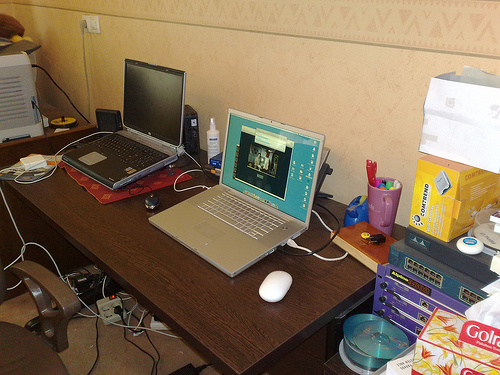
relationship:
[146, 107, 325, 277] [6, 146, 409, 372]
laptop on table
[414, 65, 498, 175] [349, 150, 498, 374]
box on boxes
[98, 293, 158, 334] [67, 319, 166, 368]
plugs on floor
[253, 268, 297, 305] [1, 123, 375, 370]
cordless mouse on table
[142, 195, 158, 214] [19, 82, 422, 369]
mouse on table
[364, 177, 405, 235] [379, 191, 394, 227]
cup with handle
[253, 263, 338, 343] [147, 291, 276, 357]
cordless mouse on desk top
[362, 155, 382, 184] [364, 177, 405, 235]
scissors in cup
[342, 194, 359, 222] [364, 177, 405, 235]
tape dispenser next to cup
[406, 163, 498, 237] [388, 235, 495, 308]
box stacked on box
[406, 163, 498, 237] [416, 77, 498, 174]
box stacked under box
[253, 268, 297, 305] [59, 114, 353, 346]
cordless mouse on desk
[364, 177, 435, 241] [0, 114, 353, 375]
cup on desk